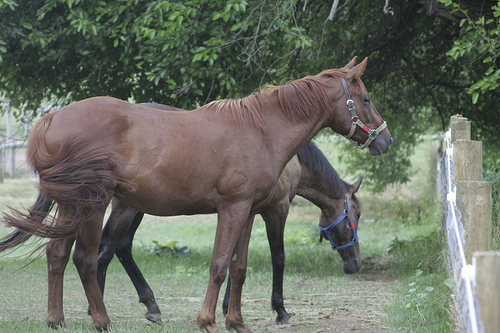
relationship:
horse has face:
[27, 55, 393, 331] [352, 70, 393, 158]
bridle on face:
[340, 77, 388, 149] [352, 70, 393, 158]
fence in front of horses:
[432, 106, 498, 331] [4, 51, 408, 331]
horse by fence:
[27, 55, 393, 331] [439, 107, 490, 302]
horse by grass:
[264, 139, 366, 321] [332, 266, 425, 327]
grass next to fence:
[395, 220, 440, 324] [435, 110, 495, 331]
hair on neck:
[203, 75, 330, 126] [211, 71, 340, 165]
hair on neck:
[304, 140, 349, 201] [211, 71, 340, 165]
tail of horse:
[6, 114, 121, 246] [27, 55, 393, 331]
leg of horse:
[194, 195, 255, 330] [27, 55, 393, 331]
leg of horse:
[197, 199, 255, 332] [27, 55, 393, 331]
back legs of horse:
[44, 186, 111, 331] [27, 55, 393, 331]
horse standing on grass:
[27, 55, 393, 331] [1, 133, 459, 330]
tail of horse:
[1, 191, 48, 256] [270, 142, 369, 325]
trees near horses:
[3, 4, 495, 253] [4, 51, 408, 331]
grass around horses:
[395, 220, 440, 324] [4, 51, 408, 331]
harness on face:
[312, 192, 360, 270] [336, 179, 371, 283]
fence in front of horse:
[432, 106, 498, 331] [0, 50, 403, 332]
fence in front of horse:
[432, 106, 498, 331] [78, 119, 375, 324]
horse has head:
[27, 55, 393, 331] [328, 57, 393, 156]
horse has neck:
[27, 55, 393, 331] [244, 90, 329, 145]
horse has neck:
[264, 139, 366, 321] [291, 148, 343, 210]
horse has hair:
[27, 55, 393, 331] [206, 66, 348, 131]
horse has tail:
[27, 55, 393, 331] [0, 110, 118, 206]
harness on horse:
[317, 192, 360, 270] [78, 119, 375, 324]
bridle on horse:
[333, 77, 390, 147] [27, 55, 393, 331]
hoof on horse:
[140, 308, 167, 328] [27, 55, 393, 331]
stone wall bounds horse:
[431, 110, 498, 331] [27, 55, 393, 331]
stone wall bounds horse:
[431, 110, 498, 331] [80, 133, 361, 325]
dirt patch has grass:
[298, 275, 389, 332] [1, 133, 459, 330]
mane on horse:
[302, 140, 366, 206] [289, 147, 371, 317]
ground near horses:
[4, 104, 444, 324] [31, 67, 426, 314]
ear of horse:
[350, 56, 369, 81] [27, 55, 393, 331]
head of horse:
[322, 53, 394, 154] [134, 91, 384, 291]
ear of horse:
[350, 171, 362, 199] [94, 99, 364, 325]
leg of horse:
[197, 199, 255, 332] [22, 47, 409, 297]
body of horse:
[58, 87, 310, 234] [27, 55, 393, 331]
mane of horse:
[248, 76, 331, 136] [27, 55, 393, 331]